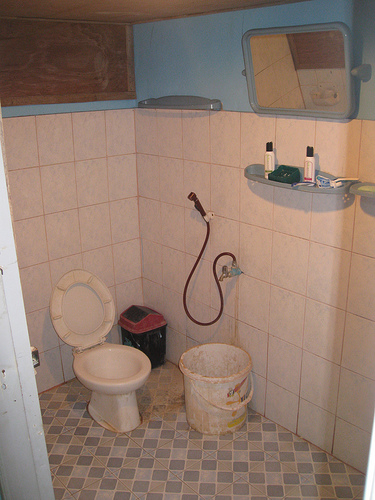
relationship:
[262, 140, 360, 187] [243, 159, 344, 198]
toiletries on shelf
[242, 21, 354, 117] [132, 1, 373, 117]
mirror on wall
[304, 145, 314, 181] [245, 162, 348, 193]
toiletrie on shelf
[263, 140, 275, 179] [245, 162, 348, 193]
toiletries on shelf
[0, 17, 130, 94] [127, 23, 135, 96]
wooden panel on wall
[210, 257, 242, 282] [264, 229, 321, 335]
faucet on wall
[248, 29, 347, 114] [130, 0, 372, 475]
mirror on wall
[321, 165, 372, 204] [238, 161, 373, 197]
toothpaste on shelf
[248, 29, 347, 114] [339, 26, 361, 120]
mirror has trim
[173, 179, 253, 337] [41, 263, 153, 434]
fountain beside toilet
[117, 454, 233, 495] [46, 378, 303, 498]
tiles on floor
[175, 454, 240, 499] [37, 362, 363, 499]
tile on floor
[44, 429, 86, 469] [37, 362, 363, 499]
tile on floor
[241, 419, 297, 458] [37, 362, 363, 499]
tile on floor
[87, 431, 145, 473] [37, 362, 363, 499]
tile on floor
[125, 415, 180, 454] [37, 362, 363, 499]
tile on floor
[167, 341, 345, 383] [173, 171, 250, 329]
bucket used as shower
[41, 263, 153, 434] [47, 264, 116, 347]
toilet with seat up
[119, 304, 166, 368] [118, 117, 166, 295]
garbage bin in corner